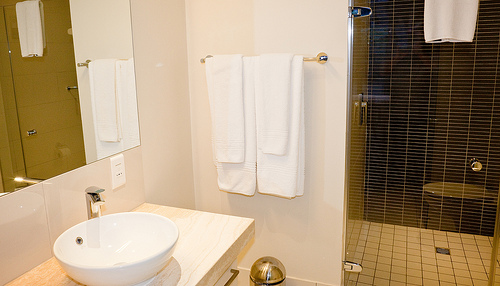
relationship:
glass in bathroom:
[2, 1, 142, 196] [6, 2, 496, 284]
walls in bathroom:
[141, 0, 341, 284] [6, 2, 496, 284]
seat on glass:
[421, 178, 487, 220] [342, 1, 499, 282]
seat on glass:
[421, 178, 487, 220] [2, 1, 142, 196]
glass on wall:
[2, 1, 142, 196] [0, 4, 192, 269]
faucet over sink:
[83, 182, 113, 222] [43, 205, 201, 284]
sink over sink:
[52, 212, 180, 286] [52, 203, 182, 283]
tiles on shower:
[367, 230, 430, 282] [347, 7, 498, 282]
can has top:
[251, 254, 286, 283] [249, 255, 283, 277]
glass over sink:
[2, 1, 142, 196] [52, 203, 182, 283]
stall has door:
[348, 0, 493, 284] [340, 2, 499, 284]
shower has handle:
[359, 12, 496, 273] [344, 87, 373, 129]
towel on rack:
[201, 52, 261, 200] [195, 53, 327, 64]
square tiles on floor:
[347, 215, 497, 284] [236, 216, 499, 284]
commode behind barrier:
[418, 179, 498, 224] [351, 11, 496, 283]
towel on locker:
[9, 0, 50, 60] [27, 61, 92, 161]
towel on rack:
[253, 52, 305, 201] [182, 51, 330, 67]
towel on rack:
[201, 50, 261, 199] [182, 51, 330, 67]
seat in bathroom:
[408, 168, 487, 220] [73, 66, 343, 275]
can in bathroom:
[251, 254, 286, 283] [67, 90, 326, 253]